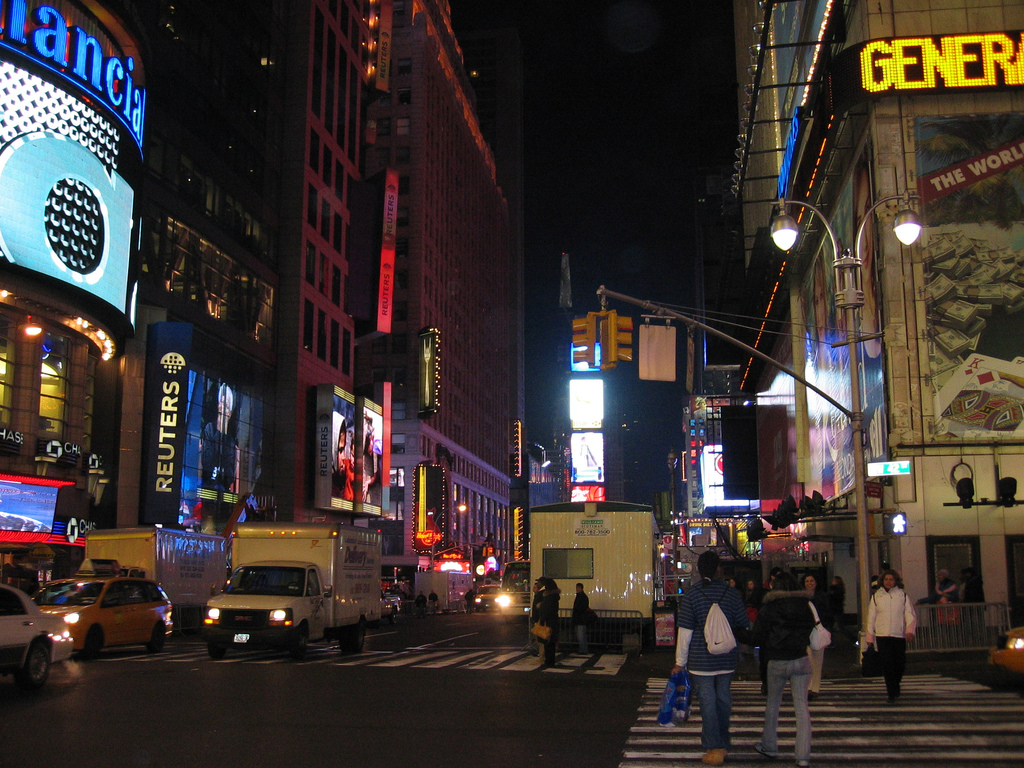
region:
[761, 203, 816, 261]
a light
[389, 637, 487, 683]
the crosswalk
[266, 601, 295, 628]
light on the truck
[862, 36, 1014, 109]
a sign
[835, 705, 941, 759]
white lines in the street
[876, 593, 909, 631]
a white jacket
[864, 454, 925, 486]
a street sign that is green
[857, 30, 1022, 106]
black digital sign with yellow text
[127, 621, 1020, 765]
white lines on the street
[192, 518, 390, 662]
white box truck on the street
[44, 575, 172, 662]
yellow car on the street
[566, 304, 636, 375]
traffic signals hanging above the street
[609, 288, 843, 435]
pole the traffic signals are attached to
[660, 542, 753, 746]
man wearing white backpack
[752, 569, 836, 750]
woman carrying white purse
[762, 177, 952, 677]
silver pole with two street lights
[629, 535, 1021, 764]
People crossing the street.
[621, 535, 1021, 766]
People in a crosswalk.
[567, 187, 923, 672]
Pole with a traffic light and street lights on it.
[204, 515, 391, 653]
A white panel truck.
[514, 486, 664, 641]
A white trailer.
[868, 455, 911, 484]
A green street sign.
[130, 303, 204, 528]
A sign for Reuters.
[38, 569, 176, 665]
A yellow van.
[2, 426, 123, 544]
Multiple signs for Chase bank.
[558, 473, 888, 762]
People walking across the stret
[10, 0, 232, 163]
The sign has blue letters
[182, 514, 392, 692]
The white truck has two headlights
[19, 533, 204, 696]
The taxi cab is yellow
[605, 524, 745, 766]
The person is wearing a white backpack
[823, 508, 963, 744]
The person is wearing a white coat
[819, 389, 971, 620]
The green street sign is on a metal pole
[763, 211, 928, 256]
Street lights on a pole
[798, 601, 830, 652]
A bag on a person's shoulder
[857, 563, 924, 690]
A person in a white coat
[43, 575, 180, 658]
A yellow car on a street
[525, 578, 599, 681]
People standing in a crosswalk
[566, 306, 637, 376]
A yellow painted traffic signal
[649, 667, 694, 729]
A blue bag in a person's hand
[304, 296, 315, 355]
glass window on the building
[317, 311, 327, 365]
glass window on the building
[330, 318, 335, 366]
glass window on the building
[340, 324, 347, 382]
glass window on the building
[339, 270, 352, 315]
glass window on the building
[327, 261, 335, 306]
glass window on the building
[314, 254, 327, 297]
glass window on the building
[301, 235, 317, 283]
glass window on the building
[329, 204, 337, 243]
glass window on the building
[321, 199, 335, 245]
glass window on the building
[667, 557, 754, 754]
A person is standing up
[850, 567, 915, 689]
A person is standing up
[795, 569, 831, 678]
A person is standing up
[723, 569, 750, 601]
A person is standing up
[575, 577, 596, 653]
A person is standing up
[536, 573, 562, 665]
A person is standing up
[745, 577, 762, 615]
A person is standing up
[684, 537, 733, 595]
the head of a man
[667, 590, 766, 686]
the shirt of a man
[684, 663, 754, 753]
the pants of a man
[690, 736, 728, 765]
the shoes of a man